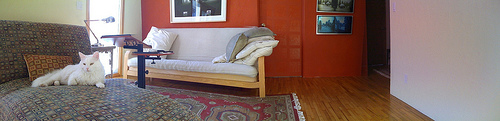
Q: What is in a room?
A: Futon.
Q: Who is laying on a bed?
A: A cat.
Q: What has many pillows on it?
A: Futon.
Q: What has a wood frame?
A: Futon.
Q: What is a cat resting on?
A: A bed.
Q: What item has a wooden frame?
A: The futon.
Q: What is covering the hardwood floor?
A: An area rug.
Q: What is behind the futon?
A: A wall.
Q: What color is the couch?
A: White.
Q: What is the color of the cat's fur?
A: White.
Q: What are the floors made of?
A: Wood.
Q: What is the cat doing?
A: Laying down.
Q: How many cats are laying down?
A: One.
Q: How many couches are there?
A: One.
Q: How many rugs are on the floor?
A: One.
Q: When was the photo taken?
A: Daytime.